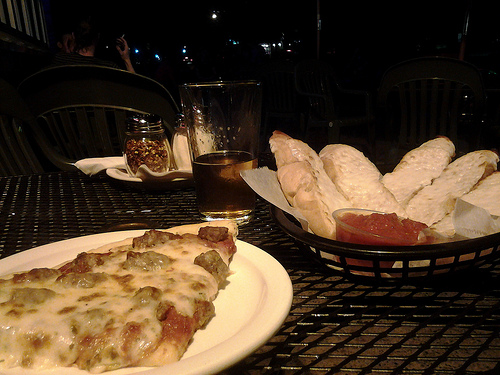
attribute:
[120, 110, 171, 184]
shaker — pepper 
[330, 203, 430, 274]
cup — small 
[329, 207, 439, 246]
sauce — DIPPING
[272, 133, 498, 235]
bread — sliced 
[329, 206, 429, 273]
sauce — red 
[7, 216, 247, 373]
pizza — slice 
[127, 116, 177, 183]
shaker — small 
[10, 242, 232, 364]
pizza — slice 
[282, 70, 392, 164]
chair — plastic , black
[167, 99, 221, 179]
shaker — full , parmesean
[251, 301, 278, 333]
plate — white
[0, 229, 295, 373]
plate — white 